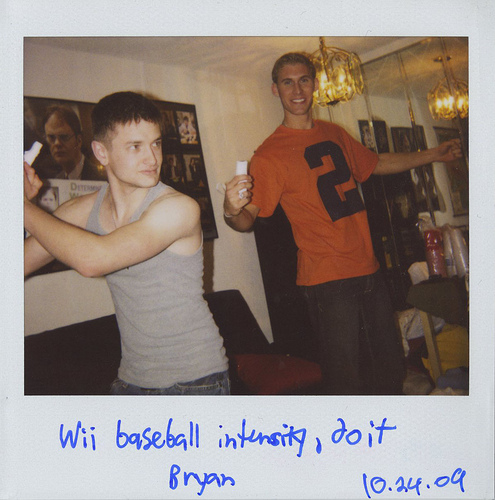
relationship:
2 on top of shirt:
[299, 137, 373, 219] [247, 119, 382, 288]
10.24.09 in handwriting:
[370, 457, 475, 497] [434, 468, 455, 490]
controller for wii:
[230, 156, 255, 211] [238, 183, 256, 209]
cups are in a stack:
[417, 225, 449, 273] [414, 217, 443, 248]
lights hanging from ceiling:
[323, 49, 368, 108] [171, 40, 244, 85]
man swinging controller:
[77, 84, 226, 389] [230, 156, 255, 211]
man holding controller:
[77, 84, 226, 389] [230, 156, 255, 211]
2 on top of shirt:
[299, 137, 373, 219] [290, 124, 366, 274]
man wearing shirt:
[77, 84, 226, 389] [290, 124, 366, 274]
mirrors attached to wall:
[386, 106, 456, 214] [210, 88, 246, 118]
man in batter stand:
[77, 84, 226, 389] [16, 135, 217, 269]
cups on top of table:
[417, 225, 449, 273] [399, 277, 455, 303]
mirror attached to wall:
[358, 97, 429, 150] [210, 88, 246, 118]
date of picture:
[370, 457, 475, 497] [77, 30, 467, 414]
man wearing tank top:
[77, 84, 226, 389] [99, 193, 228, 384]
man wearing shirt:
[252, 54, 399, 320] [290, 124, 366, 274]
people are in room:
[77, 30, 467, 414] [288, 33, 446, 110]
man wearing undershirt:
[77, 84, 226, 389] [118, 269, 247, 385]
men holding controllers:
[94, 67, 368, 331] [13, 114, 267, 196]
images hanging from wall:
[165, 99, 234, 192] [210, 88, 246, 118]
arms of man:
[5, 198, 145, 260] [77, 84, 226, 389]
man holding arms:
[77, 84, 226, 389] [5, 198, 145, 260]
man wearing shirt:
[252, 54, 399, 320] [247, 119, 382, 288]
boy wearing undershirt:
[77, 84, 226, 389] [118, 269, 247, 385]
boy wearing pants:
[252, 54, 399, 320] [297, 282, 400, 373]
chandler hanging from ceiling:
[410, 48, 460, 124] [171, 40, 244, 85]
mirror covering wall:
[358, 97, 429, 150] [210, 88, 246, 118]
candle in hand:
[441, 123, 449, 157] [412, 125, 467, 165]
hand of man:
[412, 125, 467, 165] [77, 84, 226, 389]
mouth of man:
[293, 97, 310, 105] [77, 84, 226, 389]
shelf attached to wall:
[408, 275, 474, 326] [210, 88, 246, 118]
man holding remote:
[77, 84, 226, 389] [230, 156, 255, 211]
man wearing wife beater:
[77, 84, 226, 389] [99, 193, 228, 384]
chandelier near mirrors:
[308, 40, 400, 127] [386, 106, 456, 214]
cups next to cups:
[417, 225, 449, 273] [403, 238, 429, 280]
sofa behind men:
[29, 312, 272, 402] [94, 67, 368, 331]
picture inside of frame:
[23, 84, 91, 174] [152, 97, 229, 237]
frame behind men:
[152, 97, 229, 237] [94, 67, 368, 331]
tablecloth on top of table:
[429, 301, 458, 318] [399, 277, 455, 303]